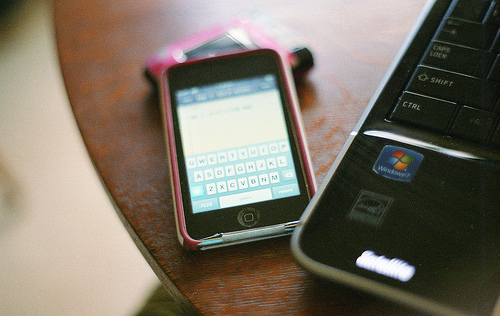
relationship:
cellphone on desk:
[157, 47, 317, 253] [52, 0, 499, 314]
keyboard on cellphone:
[184, 139, 296, 195] [157, 47, 317, 253]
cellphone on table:
[157, 47, 317, 253] [52, 0, 499, 314]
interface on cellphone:
[176, 72, 304, 217] [157, 47, 317, 253]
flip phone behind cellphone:
[129, 12, 325, 92] [157, 47, 317, 253]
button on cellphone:
[234, 205, 268, 226] [157, 47, 317, 253]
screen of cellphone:
[176, 72, 304, 217] [157, 47, 317, 253]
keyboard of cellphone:
[184, 139, 296, 195] [157, 47, 317, 253]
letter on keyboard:
[261, 172, 271, 187] [184, 139, 296, 195]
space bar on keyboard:
[219, 187, 276, 213] [184, 139, 296, 195]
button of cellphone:
[234, 205, 268, 226] [157, 47, 317, 253]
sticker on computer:
[365, 142, 429, 187] [276, 2, 495, 314]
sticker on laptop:
[344, 189, 398, 235] [276, 2, 495, 314]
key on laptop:
[407, 58, 478, 108] [276, 2, 495, 314]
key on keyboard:
[407, 58, 478, 108] [391, 0, 500, 157]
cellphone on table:
[129, 12, 325, 92] [52, 0, 499, 314]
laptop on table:
[276, 2, 495, 314] [52, 0, 499, 314]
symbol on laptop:
[365, 142, 429, 187] [276, 2, 495, 314]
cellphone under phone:
[157, 47, 317, 253] [129, 12, 325, 92]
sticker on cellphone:
[365, 142, 429, 187] [157, 47, 317, 253]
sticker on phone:
[365, 142, 429, 187] [276, 2, 495, 314]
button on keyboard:
[384, 88, 455, 134] [391, 0, 500, 157]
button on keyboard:
[418, 40, 483, 73] [391, 0, 500, 157]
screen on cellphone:
[176, 72, 304, 217] [157, 47, 317, 253]